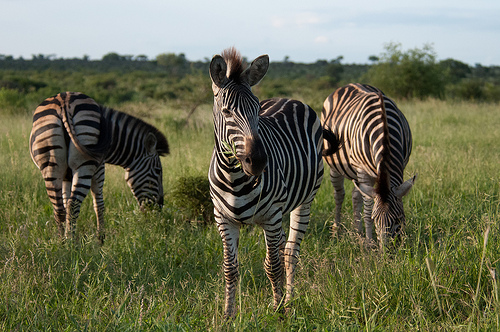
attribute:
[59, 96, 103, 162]
tail — moving, curved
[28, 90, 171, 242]
zebra — striped, black, white, grazing, eating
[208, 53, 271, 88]
ears — standing up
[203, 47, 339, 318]
zebra — striped, black, white, looking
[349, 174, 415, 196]
ears — standing up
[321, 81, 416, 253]
zebra — striped, black, white, grazing, eating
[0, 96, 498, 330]
grass — tall, high, green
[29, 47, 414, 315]
zebras — herd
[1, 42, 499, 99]
trees — bushy, green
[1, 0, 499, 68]
sky — cloudy, clear, blue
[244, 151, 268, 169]
nose — black